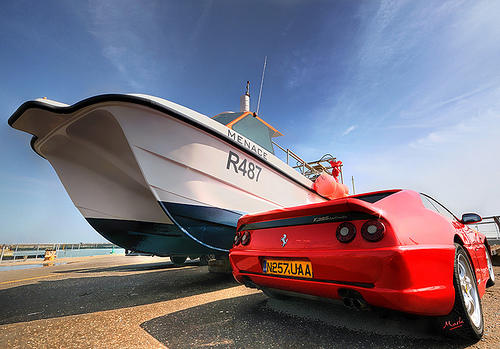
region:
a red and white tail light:
[332, 217, 357, 246]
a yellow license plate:
[256, 248, 320, 278]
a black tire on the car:
[441, 235, 488, 342]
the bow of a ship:
[3, 87, 227, 269]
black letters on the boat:
[219, 146, 266, 186]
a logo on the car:
[272, 227, 293, 249]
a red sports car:
[226, 185, 498, 345]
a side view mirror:
[459, 208, 483, 227]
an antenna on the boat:
[249, 55, 269, 117]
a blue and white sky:
[1, 0, 499, 242]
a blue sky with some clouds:
[5, 7, 479, 244]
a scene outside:
[2, 11, 435, 346]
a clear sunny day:
[10, 11, 435, 347]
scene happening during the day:
[7, 20, 480, 295]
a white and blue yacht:
[5, 62, 395, 324]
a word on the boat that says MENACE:
[224, 116, 283, 168]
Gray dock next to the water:
[14, 251, 250, 347]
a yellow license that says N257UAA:
[250, 244, 334, 294]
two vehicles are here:
[20, 30, 497, 344]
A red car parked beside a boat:
[223, 182, 493, 343]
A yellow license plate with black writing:
[250, 255, 317, 280]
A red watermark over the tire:
[433, 310, 465, 333]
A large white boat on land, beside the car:
[1, 63, 350, 281]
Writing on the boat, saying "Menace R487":
[220, 125, 271, 184]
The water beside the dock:
[4, 230, 123, 270]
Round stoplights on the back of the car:
[226, 214, 393, 250]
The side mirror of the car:
[452, 207, 487, 227]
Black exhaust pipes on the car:
[326, 287, 372, 320]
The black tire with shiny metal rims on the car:
[423, 237, 488, 344]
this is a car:
[266, 185, 478, 334]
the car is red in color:
[391, 207, 433, 266]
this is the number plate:
[258, 256, 308, 276]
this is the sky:
[305, 10, 427, 104]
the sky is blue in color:
[198, 22, 253, 65]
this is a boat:
[81, 97, 220, 238]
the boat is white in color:
[165, 131, 186, 156]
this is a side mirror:
[461, 208, 482, 229]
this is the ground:
[55, 275, 194, 345]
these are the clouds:
[423, 153, 468, 187]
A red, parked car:
[231, 175, 495, 343]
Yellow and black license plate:
[251, 240, 318, 290]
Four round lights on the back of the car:
[232, 213, 403, 257]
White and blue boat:
[12, 60, 364, 255]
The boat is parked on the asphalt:
[7, 61, 369, 286]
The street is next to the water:
[5, 227, 128, 287]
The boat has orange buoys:
[290, 156, 360, 202]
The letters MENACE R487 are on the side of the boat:
[217, 111, 272, 188]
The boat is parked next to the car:
[28, 50, 478, 336]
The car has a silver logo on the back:
[276, 227, 292, 247]